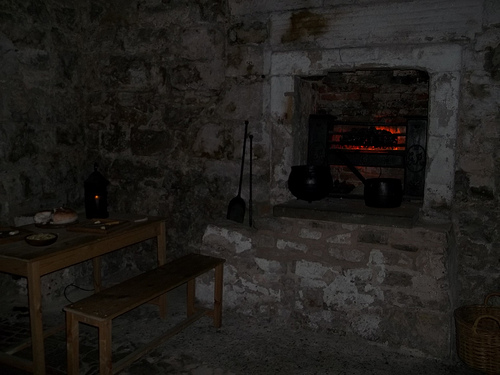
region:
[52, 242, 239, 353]
this is a bench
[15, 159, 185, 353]
this is a table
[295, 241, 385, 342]
this is a block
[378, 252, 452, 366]
this is a block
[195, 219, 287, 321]
this is a block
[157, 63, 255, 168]
this is a block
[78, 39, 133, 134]
this is a block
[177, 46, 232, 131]
this is a block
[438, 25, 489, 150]
this is a block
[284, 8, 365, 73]
this is a block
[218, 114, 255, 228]
black fire untensil for the fireplace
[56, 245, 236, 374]
brown wooden bench by the fire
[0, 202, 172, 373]
brown wooden table by the fire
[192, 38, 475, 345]
fireplace with stone mantle and hearth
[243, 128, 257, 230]
black utensil used on the fire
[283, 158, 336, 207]
cast iron pot standing by the fire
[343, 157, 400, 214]
cast iron pot standing by the fire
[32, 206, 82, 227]
plate of food on the table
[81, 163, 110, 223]
black lantern sitting on the table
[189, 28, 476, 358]
fire place with food cooking on the fire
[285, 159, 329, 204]
the blacl cauldren on the mantle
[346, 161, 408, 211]
the black pot on the fireplace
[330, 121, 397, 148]
the fire in the fireplace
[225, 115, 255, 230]
the scooper for the fireplace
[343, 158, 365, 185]
the handle of the black pot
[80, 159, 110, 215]
the lantern on the table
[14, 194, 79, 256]
food on the table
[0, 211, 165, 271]
the wooden dinner table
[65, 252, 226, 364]
the bench at the table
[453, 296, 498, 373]
the basket by the fireplace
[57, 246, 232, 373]
wooden bench on a block floor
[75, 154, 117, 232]
metal lantern on a wooden table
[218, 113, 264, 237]
metal fireplace shovel and poker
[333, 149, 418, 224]
metal cooking pot on a fireplace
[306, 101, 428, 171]
metal stove in a fire place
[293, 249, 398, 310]
Brick wall in front of a fireplace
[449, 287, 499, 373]
wicker basket in dark room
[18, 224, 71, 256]
bowl of food on a wooden table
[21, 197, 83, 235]
Plate of break on a wood table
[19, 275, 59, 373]
table leg of a wooden table